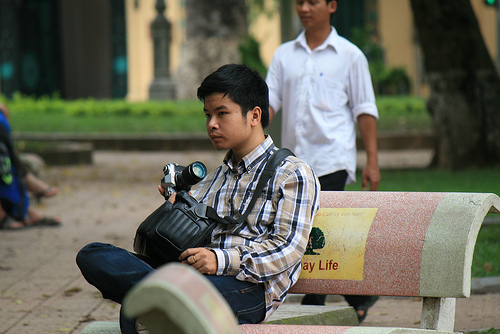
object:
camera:
[157, 158, 209, 200]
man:
[258, 0, 383, 323]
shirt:
[263, 27, 381, 179]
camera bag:
[130, 198, 239, 260]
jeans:
[74, 241, 265, 321]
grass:
[0, 95, 436, 137]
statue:
[142, 2, 178, 79]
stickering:
[299, 208, 380, 281]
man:
[76, 64, 324, 324]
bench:
[85, 188, 500, 333]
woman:
[4, 104, 67, 234]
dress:
[0, 108, 37, 224]